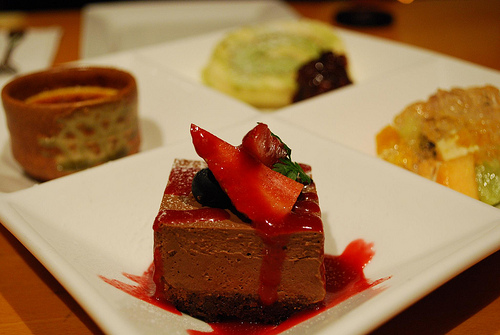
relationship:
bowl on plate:
[2, 60, 152, 191] [1, 11, 499, 334]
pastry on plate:
[145, 146, 336, 325] [1, 11, 499, 334]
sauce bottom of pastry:
[103, 240, 384, 332] [145, 146, 336, 325]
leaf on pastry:
[268, 150, 313, 191] [145, 146, 336, 325]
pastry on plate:
[368, 73, 500, 207] [1, 11, 499, 334]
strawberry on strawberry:
[233, 113, 293, 172] [181, 120, 306, 238]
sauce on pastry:
[103, 240, 384, 332] [145, 146, 336, 325]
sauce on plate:
[103, 240, 384, 332] [1, 11, 499, 334]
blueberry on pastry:
[189, 164, 236, 210] [145, 146, 336, 325]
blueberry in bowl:
[190, 167, 236, 210] [2, 60, 152, 191]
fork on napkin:
[1, 23, 27, 82] [2, 25, 66, 91]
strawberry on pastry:
[181, 120, 306, 238] [145, 146, 336, 325]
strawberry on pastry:
[233, 113, 293, 172] [145, 146, 336, 325]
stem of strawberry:
[271, 132, 293, 156] [233, 113, 293, 172]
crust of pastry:
[167, 285, 328, 330] [145, 146, 336, 325]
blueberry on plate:
[190, 167, 236, 210] [1, 11, 499, 334]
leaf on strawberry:
[268, 150, 313, 191] [181, 120, 306, 238]